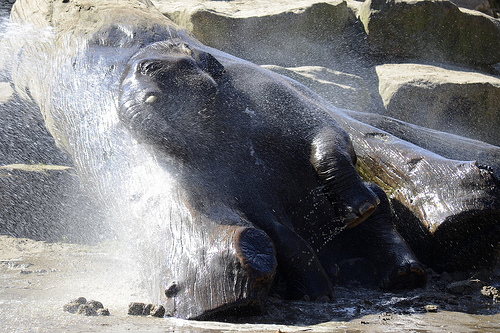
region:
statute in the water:
[74, 29, 447, 308]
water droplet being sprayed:
[38, 176, 54, 186]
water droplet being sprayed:
[102, 258, 121, 275]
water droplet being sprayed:
[117, 227, 132, 241]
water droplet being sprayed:
[136, 223, 148, 237]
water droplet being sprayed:
[58, 244, 70, 262]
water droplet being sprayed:
[105, 200, 125, 222]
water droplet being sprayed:
[70, 181, 87, 196]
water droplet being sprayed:
[32, 183, 51, 200]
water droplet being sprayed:
[46, 275, 67, 297]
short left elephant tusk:
[135, 80, 171, 116]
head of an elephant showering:
[28, 15, 229, 170]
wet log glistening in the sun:
[390, 135, 475, 211]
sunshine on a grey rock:
[380, 41, 470, 113]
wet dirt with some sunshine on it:
[7, 275, 55, 325]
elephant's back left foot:
[357, 232, 453, 298]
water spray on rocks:
[7, 125, 84, 225]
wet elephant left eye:
[136, 56, 176, 83]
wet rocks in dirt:
[50, 295, 118, 330]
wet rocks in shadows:
[431, 268, 498, 313]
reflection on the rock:
[52, 89, 204, 247]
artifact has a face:
[108, 33, 246, 132]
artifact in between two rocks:
[140, 37, 490, 307]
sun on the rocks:
[365, 46, 495, 100]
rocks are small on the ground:
[37, 281, 172, 329]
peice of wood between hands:
[277, 178, 359, 244]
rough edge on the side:
[161, 262, 246, 310]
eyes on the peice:
[133, 48, 159, 85]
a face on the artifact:
[112, 39, 230, 154]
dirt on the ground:
[375, 316, 498, 329]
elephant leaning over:
[66, 31, 432, 318]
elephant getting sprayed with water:
[7, 18, 440, 320]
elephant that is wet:
[82, 27, 454, 298]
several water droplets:
[5, 28, 281, 299]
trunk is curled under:
[123, 88, 220, 175]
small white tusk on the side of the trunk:
[144, 92, 160, 107]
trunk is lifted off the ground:
[304, 131, 379, 245]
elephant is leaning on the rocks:
[17, 8, 493, 318]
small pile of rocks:
[62, 293, 112, 318]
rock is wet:
[344, 135, 499, 232]